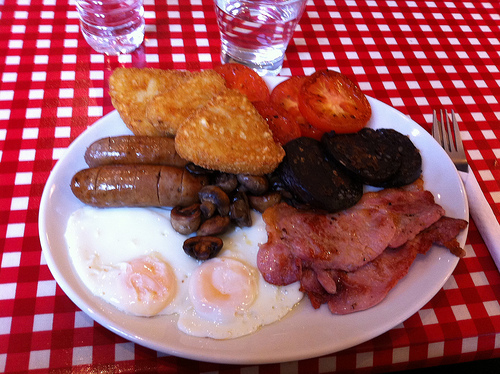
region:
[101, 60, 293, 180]
Two has browns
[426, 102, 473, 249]
Part of a fork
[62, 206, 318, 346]
Two cooked eggs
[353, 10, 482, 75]
A red and white checkered tablecloth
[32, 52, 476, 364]
A white plate full of food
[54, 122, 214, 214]
A couple of sausages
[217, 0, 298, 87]
Part of a glass of water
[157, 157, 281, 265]
A bunch of cooked mushrooms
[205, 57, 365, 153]
Five grilled tomato slices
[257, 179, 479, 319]
A few slices of ham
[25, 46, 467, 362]
a plate full of food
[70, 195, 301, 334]
two over easy cooked eggs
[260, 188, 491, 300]
two pieces of cooked ham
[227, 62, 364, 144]
sliced and grilled tomatos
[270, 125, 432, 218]
sliced pieces of burnt food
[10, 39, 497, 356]
a red and white checkered table cloth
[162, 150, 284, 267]
pile of cooked mushrooms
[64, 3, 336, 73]
two plastic bottles of water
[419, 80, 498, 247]
silverware wraped in a napkin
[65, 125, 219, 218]
two short sausage links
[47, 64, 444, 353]
The plate has breakfast food.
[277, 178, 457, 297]
Two pieces of ham on the white plate.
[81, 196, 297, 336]
Two eggs cooked soft on the plate.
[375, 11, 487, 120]
The tablecloth is red and white checkered.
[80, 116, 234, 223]
Two sausage links are on the white plate.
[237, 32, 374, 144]
Sliceds of tomatoes on the plate.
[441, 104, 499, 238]
A fork wrapped in a white napkin.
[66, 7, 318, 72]
Two glasses of water sitting on the table.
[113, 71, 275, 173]
Two hashbrowns on top of the tomato.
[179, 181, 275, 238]
Mushrooms by the hashbrown.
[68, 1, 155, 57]
water bottle on table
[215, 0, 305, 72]
cup made of glass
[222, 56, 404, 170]
red tomatoes on plate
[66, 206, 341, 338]
sunny side up eggs on plate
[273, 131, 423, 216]
sausages are on plate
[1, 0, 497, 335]
table cloth is checkered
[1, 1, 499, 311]
table cloth is red and white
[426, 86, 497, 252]
fork next to plate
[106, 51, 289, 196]
has browns next to tomatoes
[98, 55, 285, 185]
hash browns are brown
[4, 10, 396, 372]
white plate of food on table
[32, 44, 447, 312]
red and white checkered table cloth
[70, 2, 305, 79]
two bottles of water on table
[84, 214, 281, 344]
two eggs with yolks intact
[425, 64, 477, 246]
fork wrapped in napkin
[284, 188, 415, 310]
two slices of ham on plate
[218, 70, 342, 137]
four red tomatoes on plate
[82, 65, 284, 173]
two hash browns on plate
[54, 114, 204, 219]
two sausage links on plate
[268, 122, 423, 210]
two black types of food on plate